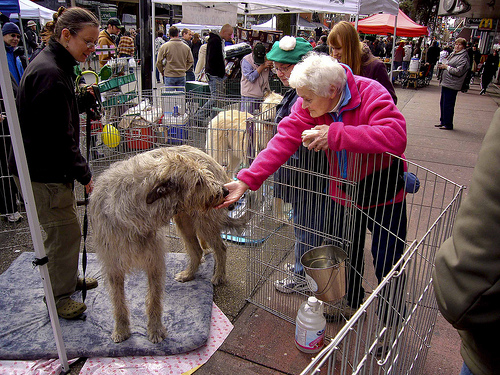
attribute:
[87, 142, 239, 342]
dog — furry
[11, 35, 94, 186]
jacket — black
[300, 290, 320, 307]
lid — white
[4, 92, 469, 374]
cage — metallic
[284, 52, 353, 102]
hair — white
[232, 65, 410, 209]
jacket — pink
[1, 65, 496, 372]
floor — stone